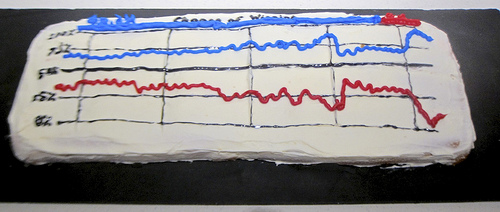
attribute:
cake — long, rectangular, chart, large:
[7, 12, 477, 168]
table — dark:
[1, 9, 500, 202]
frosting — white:
[11, 12, 476, 166]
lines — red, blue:
[56, 19, 445, 131]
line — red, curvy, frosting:
[51, 77, 445, 129]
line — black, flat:
[61, 62, 435, 73]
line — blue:
[63, 31, 434, 61]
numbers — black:
[31, 24, 80, 134]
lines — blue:
[61, 14, 439, 61]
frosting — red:
[380, 12, 422, 28]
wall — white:
[2, 1, 500, 12]